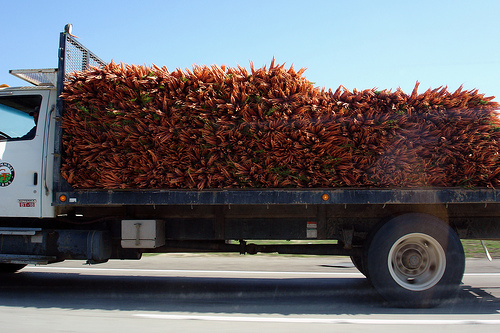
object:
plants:
[65, 65, 495, 186]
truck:
[5, 42, 64, 249]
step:
[2, 252, 64, 264]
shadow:
[6, 267, 496, 320]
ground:
[5, 251, 492, 328]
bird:
[62, 21, 76, 38]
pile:
[65, 64, 499, 194]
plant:
[136, 77, 143, 82]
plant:
[191, 94, 203, 104]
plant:
[256, 77, 268, 87]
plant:
[350, 118, 358, 123]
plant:
[398, 96, 403, 102]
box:
[118, 213, 162, 258]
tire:
[347, 217, 497, 309]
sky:
[378, 11, 445, 53]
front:
[0, 76, 61, 277]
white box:
[115, 215, 161, 254]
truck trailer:
[0, 47, 497, 316]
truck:
[2, 16, 499, 319]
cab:
[1, 133, 48, 208]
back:
[55, 22, 119, 189]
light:
[320, 193, 330, 203]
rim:
[389, 232, 441, 287]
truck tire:
[393, 212, 454, 234]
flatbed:
[52, 190, 499, 210]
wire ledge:
[7, 67, 57, 84]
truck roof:
[1, 85, 56, 94]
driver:
[12, 109, 44, 139]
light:
[55, 192, 70, 202]